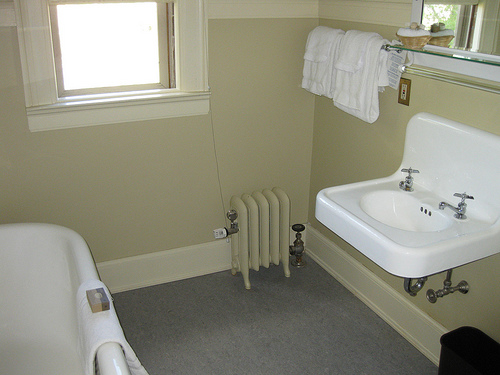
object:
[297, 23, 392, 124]
towel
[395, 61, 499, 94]
rack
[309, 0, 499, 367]
wall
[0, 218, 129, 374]
bathtub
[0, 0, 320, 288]
wall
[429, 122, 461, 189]
white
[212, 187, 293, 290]
heater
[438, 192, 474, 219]
faucet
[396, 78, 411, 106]
brown socket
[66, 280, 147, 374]
mat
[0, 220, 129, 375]
tub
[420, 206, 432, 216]
drain hole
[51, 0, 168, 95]
window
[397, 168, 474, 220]
two faucets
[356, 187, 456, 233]
sink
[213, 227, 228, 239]
white screw